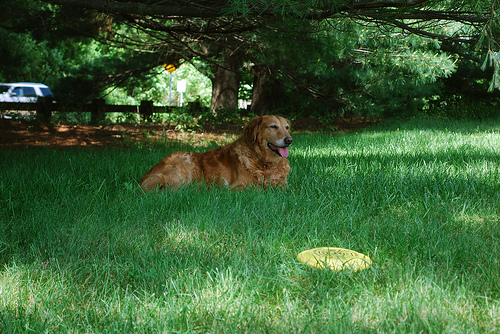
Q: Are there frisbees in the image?
A: Yes, there is a frisbee.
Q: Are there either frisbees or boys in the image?
A: Yes, there is a frisbee.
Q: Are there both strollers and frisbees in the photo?
A: No, there is a frisbee but no strollers.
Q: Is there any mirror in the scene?
A: No, there are no mirrors.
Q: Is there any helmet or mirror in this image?
A: No, there are no mirrors or helmets.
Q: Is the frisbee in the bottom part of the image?
A: Yes, the frisbee is in the bottom of the image.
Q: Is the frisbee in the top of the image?
A: No, the frisbee is in the bottom of the image.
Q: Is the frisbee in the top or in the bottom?
A: The frisbee is in the bottom of the image.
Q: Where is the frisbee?
A: The frisbee is in the grass.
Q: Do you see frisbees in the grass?
A: Yes, there is a frisbee in the grass.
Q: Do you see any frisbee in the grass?
A: Yes, there is a frisbee in the grass.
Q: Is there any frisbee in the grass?
A: Yes, there is a frisbee in the grass.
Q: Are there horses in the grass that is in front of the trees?
A: No, there is a frisbee in the grass.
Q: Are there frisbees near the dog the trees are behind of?
A: Yes, there is a frisbee near the dog.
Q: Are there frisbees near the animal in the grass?
A: Yes, there is a frisbee near the dog.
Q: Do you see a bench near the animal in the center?
A: No, there is a frisbee near the dog.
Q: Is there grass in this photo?
A: Yes, there is grass.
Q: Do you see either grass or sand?
A: Yes, there is grass.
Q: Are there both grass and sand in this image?
A: No, there is grass but no sand.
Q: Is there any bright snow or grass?
A: Yes, there is bright grass.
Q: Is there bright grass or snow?
A: Yes, there is bright grass.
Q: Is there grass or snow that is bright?
A: Yes, the grass is bright.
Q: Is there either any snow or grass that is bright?
A: Yes, the grass is bright.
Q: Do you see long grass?
A: Yes, there is long grass.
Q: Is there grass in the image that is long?
A: Yes, there is grass that is long.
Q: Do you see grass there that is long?
A: Yes, there is grass that is long.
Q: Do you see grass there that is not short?
A: Yes, there is long grass.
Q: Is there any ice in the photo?
A: No, there is no ice.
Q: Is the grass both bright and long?
A: Yes, the grass is bright and long.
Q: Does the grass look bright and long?
A: Yes, the grass is bright and long.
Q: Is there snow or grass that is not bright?
A: No, there is grass but it is bright.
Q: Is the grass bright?
A: Yes, the grass is bright.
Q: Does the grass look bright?
A: Yes, the grass is bright.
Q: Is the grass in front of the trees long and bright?
A: Yes, the grass is long and bright.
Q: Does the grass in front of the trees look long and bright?
A: Yes, the grass is long and bright.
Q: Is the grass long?
A: Yes, the grass is long.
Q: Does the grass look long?
A: Yes, the grass is long.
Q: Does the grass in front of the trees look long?
A: Yes, the grass is long.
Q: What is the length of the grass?
A: The grass is long.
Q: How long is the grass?
A: The grass is long.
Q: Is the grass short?
A: No, the grass is long.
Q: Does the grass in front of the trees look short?
A: No, the grass is long.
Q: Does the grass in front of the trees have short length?
A: No, the grass is long.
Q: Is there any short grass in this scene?
A: No, there is grass but it is long.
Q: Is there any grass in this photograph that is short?
A: No, there is grass but it is long.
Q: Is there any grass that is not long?
A: No, there is grass but it is long.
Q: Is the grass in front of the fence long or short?
A: The grass is long.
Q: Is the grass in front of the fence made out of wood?
A: Yes, the grass is in front of the fence.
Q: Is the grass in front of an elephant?
A: No, the grass is in front of the fence.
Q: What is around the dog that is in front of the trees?
A: The grass is around the dog.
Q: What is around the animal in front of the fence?
A: The grass is around the dog.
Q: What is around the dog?
A: The grass is around the dog.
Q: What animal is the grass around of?
A: The grass is around the dog.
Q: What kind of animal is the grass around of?
A: The grass is around the dog.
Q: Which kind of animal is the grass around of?
A: The grass is around the dog.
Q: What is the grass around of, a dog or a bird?
A: The grass is around a dog.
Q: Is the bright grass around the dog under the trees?
A: Yes, the grass is around the dog.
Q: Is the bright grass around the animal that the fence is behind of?
A: Yes, the grass is around the dog.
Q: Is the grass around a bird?
A: No, the grass is around the dog.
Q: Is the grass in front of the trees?
A: Yes, the grass is in front of the trees.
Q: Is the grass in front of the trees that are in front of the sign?
A: Yes, the grass is in front of the trees.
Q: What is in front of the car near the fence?
A: The grass is in front of the car.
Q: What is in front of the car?
A: The grass is in front of the car.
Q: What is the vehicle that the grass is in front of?
A: The vehicle is a car.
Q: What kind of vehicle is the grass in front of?
A: The grass is in front of the car.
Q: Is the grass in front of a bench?
A: No, the grass is in front of a car.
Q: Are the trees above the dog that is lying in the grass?
A: Yes, the trees are above the dog.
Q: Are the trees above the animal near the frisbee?
A: Yes, the trees are above the dog.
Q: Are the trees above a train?
A: No, the trees are above the dog.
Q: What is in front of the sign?
A: The trees are in front of the sign.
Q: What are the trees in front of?
A: The trees are in front of the sign.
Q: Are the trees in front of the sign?
A: Yes, the trees are in front of the sign.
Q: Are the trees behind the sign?
A: No, the trees are in front of the sign.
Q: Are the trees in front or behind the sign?
A: The trees are in front of the sign.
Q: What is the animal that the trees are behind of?
A: The animal is a dog.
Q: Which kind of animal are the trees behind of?
A: The trees are behind the dog.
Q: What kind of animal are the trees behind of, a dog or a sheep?
A: The trees are behind a dog.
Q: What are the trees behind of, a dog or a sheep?
A: The trees are behind a dog.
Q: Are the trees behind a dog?
A: Yes, the trees are behind a dog.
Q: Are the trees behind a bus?
A: No, the trees are behind a dog.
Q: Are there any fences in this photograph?
A: Yes, there is a fence.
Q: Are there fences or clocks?
A: Yes, there is a fence.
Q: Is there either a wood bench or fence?
A: Yes, there is a wood fence.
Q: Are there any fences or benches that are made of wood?
A: Yes, the fence is made of wood.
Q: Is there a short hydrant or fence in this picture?
A: Yes, there is a short fence.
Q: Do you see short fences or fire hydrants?
A: Yes, there is a short fence.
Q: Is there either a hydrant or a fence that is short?
A: Yes, the fence is short.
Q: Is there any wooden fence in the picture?
A: Yes, there is a wood fence.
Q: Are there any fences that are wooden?
A: Yes, there is a fence that is wooden.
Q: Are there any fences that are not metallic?
A: Yes, there is a wooden fence.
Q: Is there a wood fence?
A: Yes, there is a fence that is made of wood.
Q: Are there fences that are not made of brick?
A: Yes, there is a fence that is made of wood.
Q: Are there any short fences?
A: Yes, there is a short fence.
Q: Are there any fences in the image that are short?
A: Yes, there is a fence that is short.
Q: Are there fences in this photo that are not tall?
A: Yes, there is a short fence.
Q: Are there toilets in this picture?
A: No, there are no toilets.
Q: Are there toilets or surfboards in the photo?
A: No, there are no toilets or surfboards.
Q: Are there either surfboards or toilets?
A: No, there are no toilets or surfboards.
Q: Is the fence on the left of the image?
A: Yes, the fence is on the left of the image.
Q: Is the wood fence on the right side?
A: No, the fence is on the left of the image.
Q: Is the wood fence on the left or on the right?
A: The fence is on the left of the image.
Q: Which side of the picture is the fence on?
A: The fence is on the left of the image.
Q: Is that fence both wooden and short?
A: Yes, the fence is wooden and short.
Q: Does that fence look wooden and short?
A: Yes, the fence is wooden and short.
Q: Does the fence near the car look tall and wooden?
A: No, the fence is wooden but short.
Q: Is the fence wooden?
A: Yes, the fence is wooden.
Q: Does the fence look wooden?
A: Yes, the fence is wooden.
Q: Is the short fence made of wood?
A: Yes, the fence is made of wood.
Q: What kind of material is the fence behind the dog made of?
A: The fence is made of wood.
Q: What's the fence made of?
A: The fence is made of wood.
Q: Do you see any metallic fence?
A: No, there is a fence but it is wooden.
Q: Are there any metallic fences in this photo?
A: No, there is a fence but it is wooden.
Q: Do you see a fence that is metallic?
A: No, there is a fence but it is wooden.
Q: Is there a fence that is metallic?
A: No, there is a fence but it is wooden.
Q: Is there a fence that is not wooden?
A: No, there is a fence but it is wooden.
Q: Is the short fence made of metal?
A: No, the fence is made of wood.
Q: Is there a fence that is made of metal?
A: No, there is a fence but it is made of wood.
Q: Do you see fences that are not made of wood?
A: No, there is a fence but it is made of wood.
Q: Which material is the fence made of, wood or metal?
A: The fence is made of wood.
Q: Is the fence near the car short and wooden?
A: Yes, the fence is short and wooden.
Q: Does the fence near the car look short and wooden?
A: Yes, the fence is short and wooden.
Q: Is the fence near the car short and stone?
A: No, the fence is short but wooden.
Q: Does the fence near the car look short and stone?
A: No, the fence is short but wooden.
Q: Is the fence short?
A: Yes, the fence is short.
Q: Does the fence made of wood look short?
A: Yes, the fence is short.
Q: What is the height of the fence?
A: The fence is short.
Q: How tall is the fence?
A: The fence is short.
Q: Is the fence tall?
A: No, the fence is short.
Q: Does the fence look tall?
A: No, the fence is short.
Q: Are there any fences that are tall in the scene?
A: No, there is a fence but it is short.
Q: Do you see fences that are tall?
A: No, there is a fence but it is short.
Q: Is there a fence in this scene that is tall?
A: No, there is a fence but it is short.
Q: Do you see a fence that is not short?
A: No, there is a fence but it is short.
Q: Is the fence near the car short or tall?
A: The fence is short.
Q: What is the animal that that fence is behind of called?
A: The animal is a dog.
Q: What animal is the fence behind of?
A: The fence is behind the dog.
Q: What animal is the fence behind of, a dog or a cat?
A: The fence is behind a dog.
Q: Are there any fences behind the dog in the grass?
A: Yes, there is a fence behind the dog.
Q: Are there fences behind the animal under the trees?
A: Yes, there is a fence behind the dog.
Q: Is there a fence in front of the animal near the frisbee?
A: No, the fence is behind the dog.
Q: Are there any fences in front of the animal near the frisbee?
A: No, the fence is behind the dog.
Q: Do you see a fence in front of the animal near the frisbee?
A: No, the fence is behind the dog.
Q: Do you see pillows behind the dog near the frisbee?
A: No, there is a fence behind the dog.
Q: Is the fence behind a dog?
A: Yes, the fence is behind a dog.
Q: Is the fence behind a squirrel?
A: No, the fence is behind a dog.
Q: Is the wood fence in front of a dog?
A: No, the fence is behind a dog.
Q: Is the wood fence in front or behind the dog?
A: The fence is behind the dog.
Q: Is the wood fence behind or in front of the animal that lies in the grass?
A: The fence is behind the dog.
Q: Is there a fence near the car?
A: Yes, there is a fence near the car.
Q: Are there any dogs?
A: Yes, there is a dog.